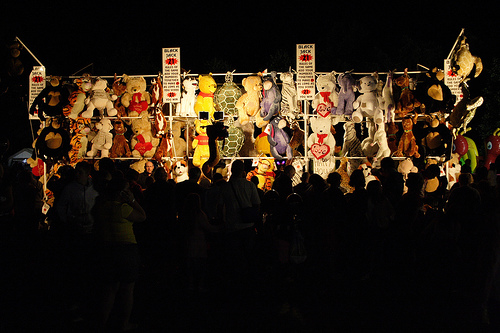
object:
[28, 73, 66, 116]
animals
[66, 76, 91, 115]
tiger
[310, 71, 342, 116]
white bear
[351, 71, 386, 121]
white bear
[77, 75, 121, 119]
white bear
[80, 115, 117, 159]
white bear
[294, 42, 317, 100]
sign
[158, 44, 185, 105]
sign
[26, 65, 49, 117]
sign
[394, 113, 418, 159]
stuffed animals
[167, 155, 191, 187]
stuffed animals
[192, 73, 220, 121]
doll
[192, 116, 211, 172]
plushies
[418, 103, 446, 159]
stuffed animals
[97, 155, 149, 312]
woman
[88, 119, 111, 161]
plush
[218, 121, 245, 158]
green turtle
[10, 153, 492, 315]
people plushies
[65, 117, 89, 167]
tigger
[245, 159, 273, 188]
tigger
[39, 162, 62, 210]
tigger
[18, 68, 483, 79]
rack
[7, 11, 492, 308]
scene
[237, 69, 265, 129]
ski equipment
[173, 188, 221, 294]
little girl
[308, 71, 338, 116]
stuffed animal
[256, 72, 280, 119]
stuffed animal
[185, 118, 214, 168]
stuffed animal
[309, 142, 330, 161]
heart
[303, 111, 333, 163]
bear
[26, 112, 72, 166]
brown monkey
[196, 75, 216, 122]
stuffed animal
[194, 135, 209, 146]
red t-shirt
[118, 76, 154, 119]
teddy bear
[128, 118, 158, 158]
teddy bear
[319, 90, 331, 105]
bow tie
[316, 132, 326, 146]
bow tie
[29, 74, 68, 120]
shape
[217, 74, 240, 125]
animal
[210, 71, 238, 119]
hanging up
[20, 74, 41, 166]
edge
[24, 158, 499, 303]
front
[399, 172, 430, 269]
people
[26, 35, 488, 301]
outdoor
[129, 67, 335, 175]
light